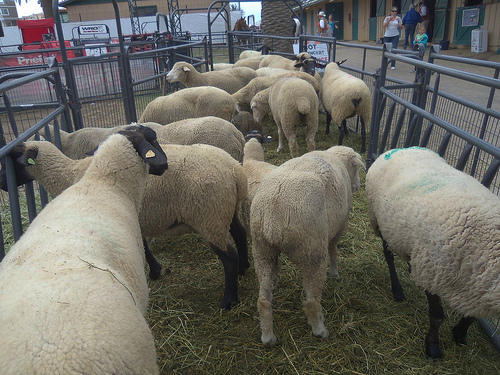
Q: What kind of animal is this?
A: Sheep.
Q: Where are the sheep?
A: Metal pen.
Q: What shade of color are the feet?
A: Brown.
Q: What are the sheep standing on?
A: Hay.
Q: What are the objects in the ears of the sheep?
A: Tags.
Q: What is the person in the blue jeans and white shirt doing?
A: Walking down a sidewalk.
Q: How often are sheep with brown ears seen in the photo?
A: Four times.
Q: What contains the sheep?
A: Fence.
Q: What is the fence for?
A: Containing the sheep.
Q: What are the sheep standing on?
A: Hay.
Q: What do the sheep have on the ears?
A: Tags.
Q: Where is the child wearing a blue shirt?
A: Top right of image.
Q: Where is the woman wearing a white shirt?
A: Top right of image.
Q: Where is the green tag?
A: Far left center.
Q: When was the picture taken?
A: Daytime.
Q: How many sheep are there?
A: Sixteen.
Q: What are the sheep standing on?
A: Straw.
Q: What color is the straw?
A: Yellow.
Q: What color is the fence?
A: Black.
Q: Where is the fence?
A: Around the sheep.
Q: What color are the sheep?
A: White and black.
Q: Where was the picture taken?
A: At a farm.